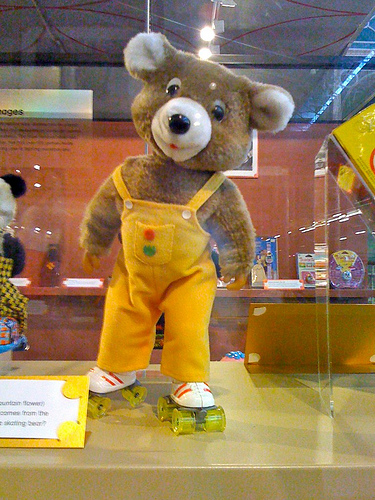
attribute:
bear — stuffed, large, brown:
[89, 33, 294, 408]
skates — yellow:
[88, 386, 224, 435]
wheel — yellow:
[173, 409, 194, 433]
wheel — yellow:
[202, 406, 226, 433]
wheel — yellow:
[123, 383, 145, 406]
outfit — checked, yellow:
[97, 168, 228, 384]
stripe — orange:
[179, 387, 193, 399]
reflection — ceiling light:
[214, 50, 245, 67]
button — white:
[126, 200, 134, 209]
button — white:
[183, 209, 193, 219]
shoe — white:
[87, 369, 137, 392]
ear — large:
[248, 82, 295, 134]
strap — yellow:
[112, 170, 132, 201]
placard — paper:
[0, 374, 90, 448]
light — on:
[200, 25, 216, 41]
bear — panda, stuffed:
[0, 173, 24, 280]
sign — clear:
[0, 88, 94, 122]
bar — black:
[1, 58, 128, 67]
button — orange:
[146, 230, 155, 243]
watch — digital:
[298, 271, 316, 287]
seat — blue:
[1, 338, 25, 354]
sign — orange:
[263, 277, 305, 291]